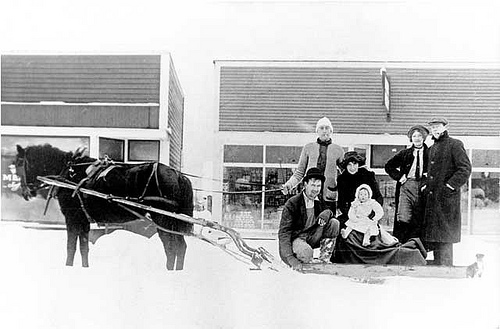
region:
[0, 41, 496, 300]
Family portrait in black and white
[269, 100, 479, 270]
Six people in this photo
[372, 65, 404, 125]
Sign on a building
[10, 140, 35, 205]
Blinders on a horse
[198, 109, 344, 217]
Man holding reigns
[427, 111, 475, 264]
Man in a trench coat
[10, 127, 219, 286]
Dark colored horse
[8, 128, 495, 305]
Horse pulling a sled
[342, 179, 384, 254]
Young child dressed in white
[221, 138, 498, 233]
Windows in a building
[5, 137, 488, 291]
a horse pulling a sledge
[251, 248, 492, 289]
sledge over the snow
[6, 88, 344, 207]
person holding the straps of a horse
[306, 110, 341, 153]
a white winter cap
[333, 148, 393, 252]
a woman holds a baby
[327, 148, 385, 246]
baby on lap of a woman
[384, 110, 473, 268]
a couple wearing black coats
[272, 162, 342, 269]
man sits squatting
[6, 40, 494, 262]
buildings behind people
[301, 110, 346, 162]
a man is smoking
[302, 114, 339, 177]
man smoking a cigerette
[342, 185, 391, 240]
baby in a dress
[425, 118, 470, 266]
man in a long overcoat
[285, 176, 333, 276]
man smiling while kneeling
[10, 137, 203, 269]
black horse hooked to sled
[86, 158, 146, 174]
bridle on the horse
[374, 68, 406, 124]
sign on the building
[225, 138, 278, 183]
windows on the building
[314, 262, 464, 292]
sled to pull the people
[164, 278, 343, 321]
white snow on the ground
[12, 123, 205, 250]
a horse pulling a buggie.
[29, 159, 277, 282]
a harness on a horse.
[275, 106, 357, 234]
a man standing in a crowd.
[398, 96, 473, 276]
a man wearing a hat.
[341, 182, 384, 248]
a baby in a woman's lap.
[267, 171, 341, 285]
a man sitting in the snow.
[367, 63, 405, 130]
a sign over an entrance.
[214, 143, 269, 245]
a window on the front of a building.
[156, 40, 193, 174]
a wall on a building.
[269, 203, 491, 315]
a sled attached to a horse.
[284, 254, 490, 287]
a sledge in front of people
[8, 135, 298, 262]
a strap of a horse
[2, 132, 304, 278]
horse pulling a sledge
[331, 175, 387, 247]
baby sits on lap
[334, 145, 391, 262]
woman holding a baby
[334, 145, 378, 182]
woman wears a black hat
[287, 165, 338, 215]
man wears a black hat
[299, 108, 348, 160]
man has a cigarette in his mouth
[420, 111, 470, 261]
man wearing a long black coat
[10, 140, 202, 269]
horse is color black